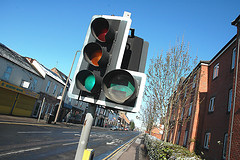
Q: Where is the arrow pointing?
A: To the right.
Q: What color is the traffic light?
A: Green.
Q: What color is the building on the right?
A: Brown.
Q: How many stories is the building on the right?
A: 3.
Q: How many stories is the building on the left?
A: 2.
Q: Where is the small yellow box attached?
A: To the traffic light pole.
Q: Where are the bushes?
A: On the left sidewalk.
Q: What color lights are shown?
A: Red, amber, green.